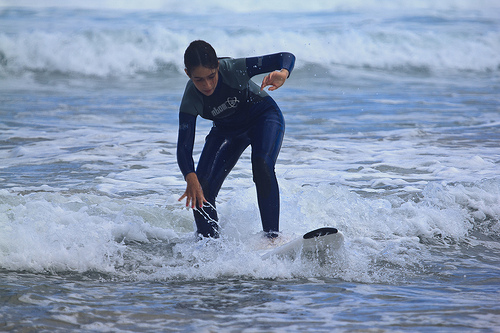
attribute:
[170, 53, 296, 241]
wet suit — blue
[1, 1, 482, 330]
blue waters — large, white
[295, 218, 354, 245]
tip — black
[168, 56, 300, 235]
blue wetsuit — blue and gray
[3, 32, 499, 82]
waves are white — big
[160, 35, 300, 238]
woman — female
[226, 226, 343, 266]
surfboard — white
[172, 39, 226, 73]
hair — dark, dark brown, thick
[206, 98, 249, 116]
brand of wetsuit — white